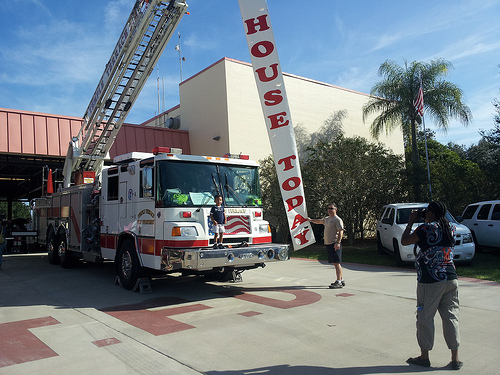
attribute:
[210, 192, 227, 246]
boy — little, standing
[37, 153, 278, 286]
truck — red, white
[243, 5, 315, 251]
sign — large, white, big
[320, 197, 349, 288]
man — standing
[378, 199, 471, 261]
car — white, parked, suv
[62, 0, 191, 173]
ladder — retractable, extended, long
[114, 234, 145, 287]
tire — secured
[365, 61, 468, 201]
tree — large, tall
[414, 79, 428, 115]
flag — american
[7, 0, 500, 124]
sky — cloudy, blue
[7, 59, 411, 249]
house — large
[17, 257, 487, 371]
ground — concrete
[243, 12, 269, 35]
letter — red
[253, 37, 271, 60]
letter — red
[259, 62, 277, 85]
letter — red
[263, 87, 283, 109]
letter — red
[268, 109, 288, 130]
letter — red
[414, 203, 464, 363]
mother — dark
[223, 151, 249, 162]
lights — red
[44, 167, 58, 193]
cone — orange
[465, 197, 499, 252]
car — parked, white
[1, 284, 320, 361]
letters — painted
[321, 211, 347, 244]
shirt — beige